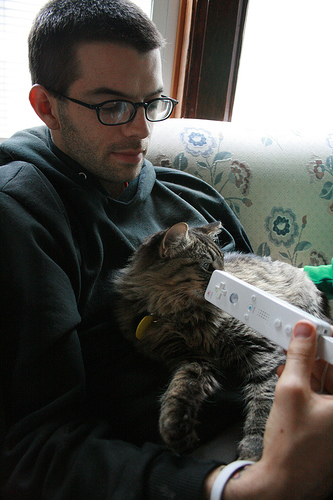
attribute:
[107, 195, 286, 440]
cat — snuggling, brown, furry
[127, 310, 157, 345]
pendant — yellow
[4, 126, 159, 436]
jacket — green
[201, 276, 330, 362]
controller — white